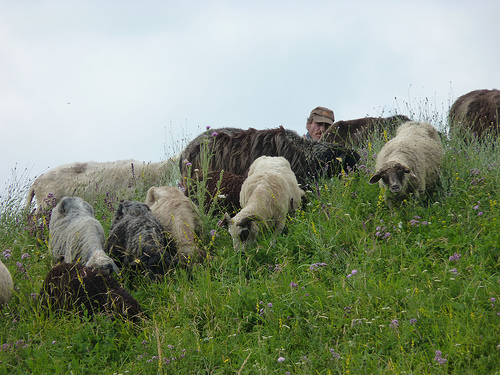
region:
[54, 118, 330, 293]
This is a picture of sheep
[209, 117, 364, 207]
This is a picture of animal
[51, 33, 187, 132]
The sky is cloudy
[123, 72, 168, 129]
The sky is empty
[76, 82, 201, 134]
There are no birds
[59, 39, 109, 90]
The sky is grey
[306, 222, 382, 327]
These are lots of weeds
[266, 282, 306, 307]
The flowers are purple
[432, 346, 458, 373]
This is a flower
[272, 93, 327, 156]
This is a man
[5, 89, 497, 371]
a herd of sheep are in the pasture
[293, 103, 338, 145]
a man is in the behind the animals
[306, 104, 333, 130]
the man is wearing a hat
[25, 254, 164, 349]
the sheep is black and feeding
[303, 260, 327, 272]
the flowers are purple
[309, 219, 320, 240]
these flowers are yellow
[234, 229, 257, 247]
this sheeps eye has a black ring around it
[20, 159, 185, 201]
the animal in back is white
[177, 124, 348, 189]
this animal is brown and has his head down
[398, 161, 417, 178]
his ears are brown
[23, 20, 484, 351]
photograph of goats grazing in field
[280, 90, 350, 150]
man behind the goats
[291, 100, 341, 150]
man wearing a brown baseball hat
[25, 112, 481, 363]
field with tall green grass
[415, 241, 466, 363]
little purple flowers in the field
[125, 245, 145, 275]
little yellow flowers in the field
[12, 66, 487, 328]
black and white goats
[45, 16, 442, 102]
sky covered with white clouds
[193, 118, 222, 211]
very tall purple flowers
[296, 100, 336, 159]
man looking directly at camera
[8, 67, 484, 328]
several animals are grazing in the pasture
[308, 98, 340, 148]
a man is with his animals in the pasture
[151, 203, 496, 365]
the pasture is filled with green grass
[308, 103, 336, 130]
the man in the pasture is wearing a hat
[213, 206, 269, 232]
this animal has horns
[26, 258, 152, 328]
the animal is black in color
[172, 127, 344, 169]
this animal has long hair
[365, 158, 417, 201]
the animal is facing the camera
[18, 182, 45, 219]
a portion of the animals tail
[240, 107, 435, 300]
the grass in the pasture is long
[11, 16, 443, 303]
A large herd of sheep.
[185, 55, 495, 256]
The sheep herder.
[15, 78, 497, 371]
A cloudy day on the farmland.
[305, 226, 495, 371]
Beautiful green grass.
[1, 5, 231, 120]
The grey skies overhead.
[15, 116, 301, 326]
Sheep skin for wool.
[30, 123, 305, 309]
Sheep grazing in the grass.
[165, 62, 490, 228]
A peeping tom.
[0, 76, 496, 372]
9 sheep on top of a grassy hill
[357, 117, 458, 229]
An onlooker